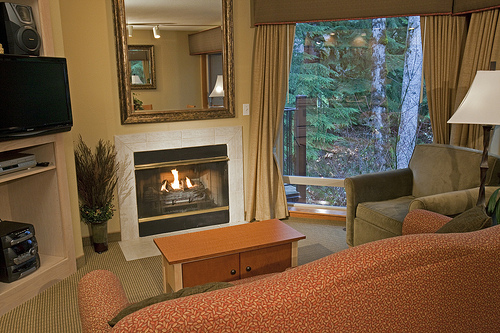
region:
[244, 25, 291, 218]
Curtain hanging down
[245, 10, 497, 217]
The curtains are brown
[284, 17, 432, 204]
Outdoor view from window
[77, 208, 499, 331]
Sofa is orange with a sprinkle pattern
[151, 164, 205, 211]
Logs are on fire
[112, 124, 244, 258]
The fireplace is white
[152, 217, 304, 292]
Table is three shades of brown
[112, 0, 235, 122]
Mirror hangs on the wall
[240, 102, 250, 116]
Light switch is white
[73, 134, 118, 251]
A plant is in a vase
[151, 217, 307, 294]
A wooden coffee table.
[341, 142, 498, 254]
A green armchair.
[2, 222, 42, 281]
A grey and black stereo.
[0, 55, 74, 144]
A black flatscreen television.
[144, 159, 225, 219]
A fire in the fireplace.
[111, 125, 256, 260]
A white framed fireplace.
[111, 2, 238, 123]
A brown large framed mirror.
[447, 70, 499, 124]
A white lamp shade.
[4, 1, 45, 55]
A speaker that goes to a stereo.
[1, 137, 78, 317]
A light brown entertainment stand.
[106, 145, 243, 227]
fire in a fire place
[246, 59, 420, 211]
tall open winow in living room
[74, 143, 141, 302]
fake plant in planter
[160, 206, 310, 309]
coffee table with two cupboards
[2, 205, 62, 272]
stereo system on entetainment center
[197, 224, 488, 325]
top of peacha nd white couch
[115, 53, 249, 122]
mirror with a silver frame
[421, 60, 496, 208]
white lamp shade with bronze stand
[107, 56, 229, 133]
reflections in a mirror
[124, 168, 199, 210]
orange flame of a smalll fire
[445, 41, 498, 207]
A white floor lamp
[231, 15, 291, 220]
A tan window curtain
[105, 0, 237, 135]
A gold/bronze mirror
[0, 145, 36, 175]
A silver dvd player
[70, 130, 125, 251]
A potted plant on the floor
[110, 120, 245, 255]
A white frame fire place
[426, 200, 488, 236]
A brown pillow on a couch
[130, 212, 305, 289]
A small wooden cabinet/table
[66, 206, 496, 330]
A red/pink couch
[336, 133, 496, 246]
A green comfortable chair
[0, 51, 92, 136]
A TV hanging on the wall.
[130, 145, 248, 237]
A fire in the fireplace.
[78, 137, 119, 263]
A plant in the corner.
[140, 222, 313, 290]
A table in the middle of the room.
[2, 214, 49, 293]
A stereo on bottom shelf.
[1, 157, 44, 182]
DVD player on the shelf.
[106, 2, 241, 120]
Mirror on the wall.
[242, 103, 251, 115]
A light switch on the wall.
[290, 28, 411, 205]
A window in the room.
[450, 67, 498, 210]
A lamp on the table.